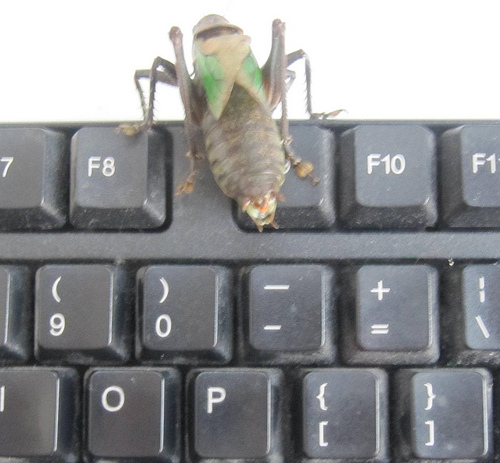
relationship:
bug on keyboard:
[126, 10, 338, 228] [5, 117, 499, 448]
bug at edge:
[126, 10, 338, 228] [5, 114, 499, 136]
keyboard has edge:
[5, 117, 499, 448] [5, 114, 499, 136]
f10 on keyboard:
[337, 123, 442, 229] [5, 117, 499, 448]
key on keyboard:
[26, 261, 133, 359] [5, 117, 499, 448]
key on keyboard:
[131, 263, 232, 358] [5, 117, 499, 448]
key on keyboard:
[346, 259, 442, 357] [5, 117, 499, 448]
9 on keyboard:
[28, 262, 128, 362] [5, 117, 499, 448]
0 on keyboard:
[129, 263, 229, 359] [5, 117, 499, 448]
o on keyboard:
[80, 363, 187, 449] [5, 117, 499, 448]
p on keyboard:
[193, 363, 283, 454] [5, 117, 499, 448]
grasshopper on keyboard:
[126, 10, 338, 228] [5, 117, 499, 448]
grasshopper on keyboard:
[119, 1, 345, 243] [5, 117, 499, 448]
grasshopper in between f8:
[119, 1, 345, 243] [71, 122, 169, 223]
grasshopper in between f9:
[119, 1, 345, 243] [235, 122, 341, 232]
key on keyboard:
[302, 367, 389, 454] [5, 117, 499, 448]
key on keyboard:
[403, 363, 499, 452] [5, 117, 499, 448]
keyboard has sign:
[5, 117, 499, 448] [346, 265, 438, 359]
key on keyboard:
[0, 362, 79, 459] [5, 117, 499, 448]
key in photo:
[0, 362, 79, 459] [3, 1, 495, 458]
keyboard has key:
[5, 117, 499, 448] [235, 263, 335, 365]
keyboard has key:
[5, 117, 499, 448] [337, 123, 442, 229]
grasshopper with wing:
[119, 1, 345, 243] [235, 42, 272, 112]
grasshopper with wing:
[119, 1, 345, 243] [196, 32, 249, 117]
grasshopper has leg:
[119, 1, 345, 243] [167, 22, 194, 195]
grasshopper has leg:
[119, 1, 345, 243] [126, 55, 177, 139]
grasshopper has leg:
[119, 1, 345, 243] [122, 63, 178, 134]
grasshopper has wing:
[119, 1, 345, 243] [235, 42, 272, 112]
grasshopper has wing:
[119, 1, 345, 243] [196, 32, 249, 117]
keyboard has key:
[5, 117, 499, 448] [442, 126, 500, 235]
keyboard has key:
[5, 117, 499, 448] [1, 122, 71, 224]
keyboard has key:
[5, 117, 499, 448] [193, 363, 283, 454]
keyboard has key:
[5, 117, 499, 448] [80, 363, 187, 449]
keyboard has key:
[5, 117, 499, 448] [0, 362, 79, 459]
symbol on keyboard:
[453, 263, 499, 353] [5, 117, 499, 448]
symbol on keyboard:
[346, 259, 442, 357] [5, 117, 499, 448]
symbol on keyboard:
[235, 263, 335, 365] [5, 117, 499, 448]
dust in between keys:
[5, 230, 498, 262] [0, 120, 500, 366]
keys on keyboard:
[0, 120, 500, 366] [5, 117, 499, 448]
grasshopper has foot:
[119, 1, 345, 243] [293, 157, 318, 190]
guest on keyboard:
[126, 10, 338, 228] [5, 117, 499, 448]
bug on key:
[126, 10, 338, 228] [235, 122, 341, 232]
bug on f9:
[126, 10, 338, 228] [235, 122, 341, 232]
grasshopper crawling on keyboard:
[119, 1, 345, 243] [5, 117, 499, 448]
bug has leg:
[126, 10, 338, 228] [167, 22, 194, 195]